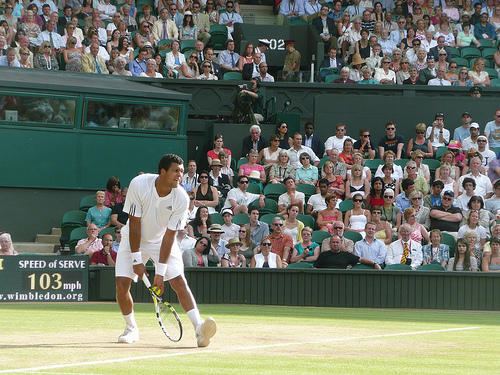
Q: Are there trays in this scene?
A: No, there are no trays.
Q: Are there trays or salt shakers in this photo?
A: No, there are no trays or salt shakers.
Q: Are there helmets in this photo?
A: No, there are no helmets.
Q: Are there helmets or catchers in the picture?
A: No, there are no helmets or catchers.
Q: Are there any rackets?
A: Yes, there is a racket.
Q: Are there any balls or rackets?
A: Yes, there is a racket.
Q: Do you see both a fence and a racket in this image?
A: No, there is a racket but no fences.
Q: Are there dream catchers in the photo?
A: No, there are no dream catchers.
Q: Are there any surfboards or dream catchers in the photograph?
A: No, there are no dream catchers or surfboards.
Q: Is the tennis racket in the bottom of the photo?
A: Yes, the tennis racket is in the bottom of the image.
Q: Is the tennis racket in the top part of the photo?
A: No, the tennis racket is in the bottom of the image.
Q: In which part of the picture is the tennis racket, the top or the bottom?
A: The tennis racket is in the bottom of the image.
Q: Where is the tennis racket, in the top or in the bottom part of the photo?
A: The tennis racket is in the bottom of the image.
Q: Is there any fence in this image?
A: No, there are no fences.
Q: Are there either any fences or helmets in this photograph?
A: No, there are no fences or helmets.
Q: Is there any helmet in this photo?
A: No, there are no helmets.